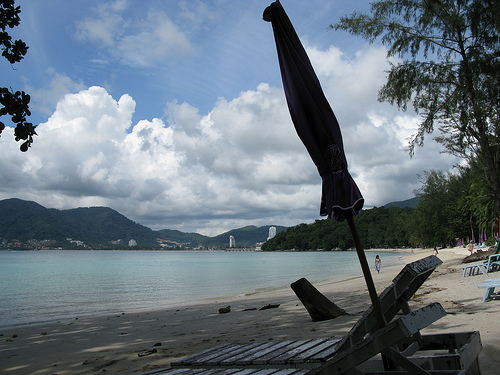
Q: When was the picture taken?
A: Dusk.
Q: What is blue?
A: Water.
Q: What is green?
A: Tree.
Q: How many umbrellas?
A: One.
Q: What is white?
A: Cloud.